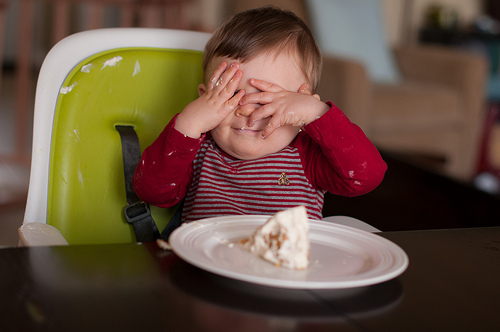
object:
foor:
[321, 147, 498, 230]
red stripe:
[271, 160, 299, 165]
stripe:
[199, 170, 206, 182]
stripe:
[300, 186, 319, 192]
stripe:
[298, 197, 322, 200]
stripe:
[310, 205, 323, 209]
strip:
[277, 150, 298, 157]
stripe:
[240, 193, 251, 197]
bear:
[278, 172, 290, 186]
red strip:
[218, 188, 252, 196]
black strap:
[114, 125, 162, 242]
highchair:
[16, 25, 213, 248]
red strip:
[291, 178, 318, 195]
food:
[240, 205, 311, 270]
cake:
[239, 205, 311, 270]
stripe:
[227, 162, 250, 169]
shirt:
[129, 100, 389, 226]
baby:
[131, 3, 388, 251]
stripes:
[205, 200, 231, 213]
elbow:
[132, 162, 186, 209]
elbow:
[337, 156, 387, 198]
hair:
[202, 3, 324, 95]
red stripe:
[241, 207, 261, 210]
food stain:
[348, 170, 361, 186]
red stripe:
[188, 202, 223, 221]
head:
[197, 4, 326, 160]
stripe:
[182, 201, 191, 210]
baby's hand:
[235, 78, 326, 140]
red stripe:
[197, 149, 226, 164]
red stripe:
[246, 163, 303, 178]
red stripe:
[234, 180, 260, 191]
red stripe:
[269, 199, 325, 205]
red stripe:
[234, 191, 246, 217]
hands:
[191, 61, 247, 133]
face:
[205, 65, 314, 160]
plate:
[168, 214, 410, 301]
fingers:
[207, 61, 245, 113]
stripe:
[208, 143, 217, 151]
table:
[0, 227, 499, 331]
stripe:
[276, 160, 292, 167]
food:
[209, 77, 222, 89]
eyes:
[228, 89, 246, 100]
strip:
[193, 159, 203, 162]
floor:
[320, 147, 498, 230]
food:
[60, 56, 141, 94]